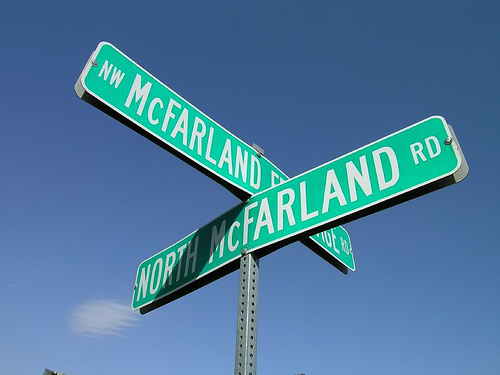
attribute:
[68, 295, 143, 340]
clouds — white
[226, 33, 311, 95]
sky — clear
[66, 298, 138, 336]
clouds — white 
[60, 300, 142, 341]
cloud — white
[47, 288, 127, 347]
clouds — white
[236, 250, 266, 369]
bar — gray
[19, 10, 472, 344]
sky — blue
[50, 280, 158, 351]
clouds — white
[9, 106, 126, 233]
sky — clear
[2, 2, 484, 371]
sky — clear, blue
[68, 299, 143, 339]
cloud — white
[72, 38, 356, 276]
street sign — white, green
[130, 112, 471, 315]
street sign — white, green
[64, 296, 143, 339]
cloud — white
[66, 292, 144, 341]
cloud — white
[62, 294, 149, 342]
cloud — white